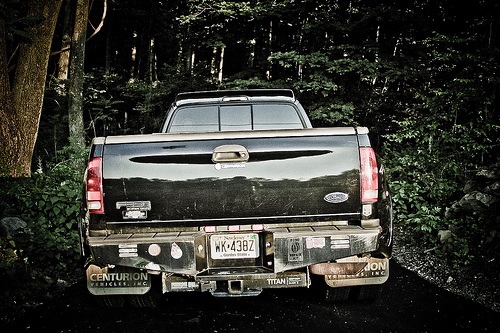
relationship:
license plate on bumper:
[211, 235, 260, 260] [85, 226, 382, 261]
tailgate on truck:
[83, 129, 379, 221] [59, 82, 404, 309]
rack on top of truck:
[177, 90, 308, 106] [130, 86, 472, 316]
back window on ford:
[169, 102, 302, 128] [74, 74, 408, 315]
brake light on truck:
[359, 147, 378, 203] [37, 38, 467, 308]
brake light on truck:
[80, 156, 120, 206] [37, 38, 467, 308]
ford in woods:
[74, 74, 408, 315] [132, 14, 373, 108]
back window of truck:
[169, 102, 302, 128] [73, 79, 398, 301]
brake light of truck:
[359, 147, 378, 203] [108, 87, 380, 276]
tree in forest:
[67, 0, 92, 156] [7, 0, 497, 323]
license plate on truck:
[211, 235, 260, 260] [73, 79, 398, 301]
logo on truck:
[323, 190, 349, 205] [73, 79, 398, 301]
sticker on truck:
[87, 262, 157, 297] [73, 79, 398, 301]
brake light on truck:
[80, 156, 120, 206] [73, 79, 398, 301]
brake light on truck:
[359, 147, 378, 203] [73, 79, 398, 301]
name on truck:
[117, 200, 149, 210] [85, 88, 390, 316]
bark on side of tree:
[21, 77, 37, 119] [11, 8, 63, 174]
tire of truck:
[96, 267, 183, 309] [73, 79, 398, 301]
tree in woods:
[67, 0, 92, 156] [4, 9, 499, 301]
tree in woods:
[2, 0, 50, 175] [4, 9, 499, 301]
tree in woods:
[54, 6, 76, 83] [4, 9, 499, 301]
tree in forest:
[382, 62, 497, 272] [7, 0, 497, 323]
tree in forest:
[227, 24, 396, 123] [7, 0, 497, 323]